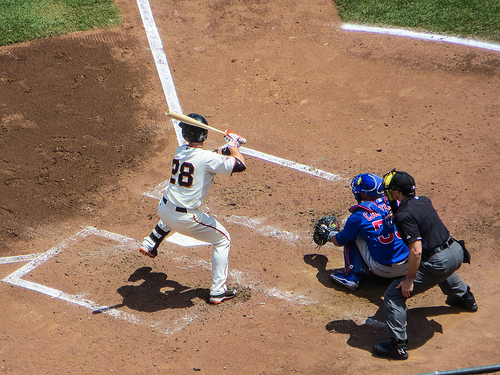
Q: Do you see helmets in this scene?
A: Yes, there is a helmet.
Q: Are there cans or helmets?
A: Yes, there is a helmet.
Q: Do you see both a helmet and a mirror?
A: No, there is a helmet but no mirrors.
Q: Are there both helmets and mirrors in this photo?
A: No, there is a helmet but no mirrors.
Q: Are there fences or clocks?
A: No, there are no fences or clocks.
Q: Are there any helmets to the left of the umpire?
A: Yes, there is a helmet to the left of the umpire.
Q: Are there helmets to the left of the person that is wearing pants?
A: Yes, there is a helmet to the left of the umpire.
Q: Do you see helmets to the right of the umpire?
A: No, the helmet is to the left of the umpire.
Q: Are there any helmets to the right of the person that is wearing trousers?
A: No, the helmet is to the left of the umpire.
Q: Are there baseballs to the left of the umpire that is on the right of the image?
A: No, there is a helmet to the left of the umpire.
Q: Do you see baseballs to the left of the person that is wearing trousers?
A: No, there is a helmet to the left of the umpire.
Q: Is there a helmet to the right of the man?
A: Yes, there is a helmet to the right of the man.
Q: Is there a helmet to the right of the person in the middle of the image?
A: Yes, there is a helmet to the right of the man.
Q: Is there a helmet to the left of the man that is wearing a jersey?
A: No, the helmet is to the right of the man.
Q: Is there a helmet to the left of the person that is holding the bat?
A: No, the helmet is to the right of the man.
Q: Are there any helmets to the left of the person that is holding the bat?
A: No, the helmet is to the right of the man.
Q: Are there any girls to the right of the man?
A: No, there is a helmet to the right of the man.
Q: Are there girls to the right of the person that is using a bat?
A: No, there is a helmet to the right of the man.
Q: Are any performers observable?
A: No, there are no performers.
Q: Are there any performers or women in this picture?
A: No, there are no performers or women.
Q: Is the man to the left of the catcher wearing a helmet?
A: Yes, the man is wearing a helmet.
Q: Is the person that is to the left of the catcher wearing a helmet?
A: Yes, the man is wearing a helmet.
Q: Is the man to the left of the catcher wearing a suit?
A: No, the man is wearing a helmet.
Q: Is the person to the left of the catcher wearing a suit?
A: No, the man is wearing a helmet.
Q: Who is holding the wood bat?
A: The man is holding the bat.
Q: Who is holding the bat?
A: The man is holding the bat.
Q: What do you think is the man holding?
A: The man is holding the bat.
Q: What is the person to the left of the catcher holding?
A: The man is holding the bat.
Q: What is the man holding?
A: The man is holding the bat.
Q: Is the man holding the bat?
A: Yes, the man is holding the bat.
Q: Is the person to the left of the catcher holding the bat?
A: Yes, the man is holding the bat.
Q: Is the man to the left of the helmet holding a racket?
A: No, the man is holding the bat.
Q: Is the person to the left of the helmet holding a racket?
A: No, the man is holding the bat.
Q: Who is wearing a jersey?
A: The man is wearing a jersey.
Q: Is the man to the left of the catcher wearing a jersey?
A: Yes, the man is wearing a jersey.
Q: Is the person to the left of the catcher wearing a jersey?
A: Yes, the man is wearing a jersey.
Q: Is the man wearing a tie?
A: No, the man is wearing a jersey.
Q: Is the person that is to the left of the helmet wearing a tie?
A: No, the man is wearing a jersey.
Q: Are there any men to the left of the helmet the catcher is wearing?
A: Yes, there is a man to the left of the helmet.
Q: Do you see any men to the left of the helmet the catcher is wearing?
A: Yes, there is a man to the left of the helmet.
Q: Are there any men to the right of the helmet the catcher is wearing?
A: No, the man is to the left of the helmet.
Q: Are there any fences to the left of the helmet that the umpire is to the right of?
A: No, there is a man to the left of the helmet.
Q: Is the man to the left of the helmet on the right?
A: Yes, the man is to the left of the helmet.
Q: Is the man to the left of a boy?
A: No, the man is to the left of the helmet.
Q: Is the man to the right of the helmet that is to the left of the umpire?
A: No, the man is to the left of the helmet.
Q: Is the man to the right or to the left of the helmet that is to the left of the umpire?
A: The man is to the left of the helmet.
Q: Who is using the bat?
A: The man is using the bat.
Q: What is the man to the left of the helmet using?
A: The man is using a bat.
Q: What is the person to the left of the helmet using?
A: The man is using a bat.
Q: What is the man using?
A: The man is using a bat.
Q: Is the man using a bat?
A: Yes, the man is using a bat.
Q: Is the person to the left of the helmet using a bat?
A: Yes, the man is using a bat.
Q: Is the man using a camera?
A: No, the man is using a bat.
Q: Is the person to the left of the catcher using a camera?
A: No, the man is using a bat.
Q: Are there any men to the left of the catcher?
A: Yes, there is a man to the left of the catcher.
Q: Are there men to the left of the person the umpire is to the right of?
A: Yes, there is a man to the left of the catcher.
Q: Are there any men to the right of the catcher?
A: No, the man is to the left of the catcher.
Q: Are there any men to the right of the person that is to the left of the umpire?
A: No, the man is to the left of the catcher.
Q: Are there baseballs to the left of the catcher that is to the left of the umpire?
A: No, there is a man to the left of the catcher.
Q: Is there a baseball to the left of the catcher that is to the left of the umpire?
A: No, there is a man to the left of the catcher.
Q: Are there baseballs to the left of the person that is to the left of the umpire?
A: No, there is a man to the left of the catcher.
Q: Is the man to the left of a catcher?
A: Yes, the man is to the left of a catcher.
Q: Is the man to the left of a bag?
A: No, the man is to the left of a catcher.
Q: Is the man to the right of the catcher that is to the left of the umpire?
A: No, the man is to the left of the catcher.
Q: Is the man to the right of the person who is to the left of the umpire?
A: No, the man is to the left of the catcher.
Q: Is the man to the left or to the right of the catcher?
A: The man is to the left of the catcher.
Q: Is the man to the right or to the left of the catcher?
A: The man is to the left of the catcher.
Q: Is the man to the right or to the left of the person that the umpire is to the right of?
A: The man is to the left of the catcher.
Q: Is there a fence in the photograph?
A: No, there are no fences.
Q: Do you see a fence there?
A: No, there are no fences.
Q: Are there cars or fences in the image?
A: No, there are no fences or cars.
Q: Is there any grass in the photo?
A: Yes, there is grass.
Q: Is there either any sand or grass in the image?
A: Yes, there is grass.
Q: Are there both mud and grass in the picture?
A: No, there is grass but no mud.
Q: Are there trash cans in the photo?
A: No, there are no trash cans.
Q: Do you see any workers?
A: No, there are no workers.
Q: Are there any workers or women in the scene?
A: No, there are no workers or women.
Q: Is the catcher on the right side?
A: Yes, the catcher is on the right of the image.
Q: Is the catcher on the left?
A: No, the catcher is on the right of the image.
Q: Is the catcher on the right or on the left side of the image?
A: The catcher is on the right of the image.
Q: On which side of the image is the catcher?
A: The catcher is on the right of the image.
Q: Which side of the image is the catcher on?
A: The catcher is on the right of the image.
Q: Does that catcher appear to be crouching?
A: Yes, the catcher is crouching.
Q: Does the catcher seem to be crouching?
A: Yes, the catcher is crouching.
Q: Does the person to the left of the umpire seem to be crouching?
A: Yes, the catcher is crouching.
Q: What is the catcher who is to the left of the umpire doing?
A: The catcher is crouching.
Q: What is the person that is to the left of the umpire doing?
A: The catcher is crouching.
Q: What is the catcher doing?
A: The catcher is crouching.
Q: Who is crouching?
A: The catcher is crouching.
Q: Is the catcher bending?
A: No, the catcher is crouching.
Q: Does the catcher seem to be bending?
A: No, the catcher is crouching.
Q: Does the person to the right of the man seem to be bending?
A: No, the catcher is crouching.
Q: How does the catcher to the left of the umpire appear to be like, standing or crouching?
A: The catcher is crouching.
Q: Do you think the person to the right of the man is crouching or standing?
A: The catcher is crouching.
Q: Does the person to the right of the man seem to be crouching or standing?
A: The catcher is crouching.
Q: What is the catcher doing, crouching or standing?
A: The catcher is crouching.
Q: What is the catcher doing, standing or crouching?
A: The catcher is crouching.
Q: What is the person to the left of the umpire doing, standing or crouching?
A: The catcher is crouching.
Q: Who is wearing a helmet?
A: The catcher is wearing a helmet.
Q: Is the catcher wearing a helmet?
A: Yes, the catcher is wearing a helmet.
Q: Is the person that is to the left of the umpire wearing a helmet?
A: Yes, the catcher is wearing a helmet.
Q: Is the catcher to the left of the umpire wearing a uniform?
A: No, the catcher is wearing a helmet.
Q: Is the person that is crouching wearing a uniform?
A: No, the catcher is wearing a helmet.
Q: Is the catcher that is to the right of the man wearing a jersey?
A: Yes, the catcher is wearing a jersey.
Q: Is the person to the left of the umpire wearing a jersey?
A: Yes, the catcher is wearing a jersey.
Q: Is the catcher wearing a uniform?
A: No, the catcher is wearing a jersey.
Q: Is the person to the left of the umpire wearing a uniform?
A: No, the catcher is wearing a jersey.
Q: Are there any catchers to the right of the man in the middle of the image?
A: Yes, there is a catcher to the right of the man.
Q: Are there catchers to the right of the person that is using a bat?
A: Yes, there is a catcher to the right of the man.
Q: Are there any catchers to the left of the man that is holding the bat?
A: No, the catcher is to the right of the man.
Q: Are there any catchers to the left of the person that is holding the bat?
A: No, the catcher is to the right of the man.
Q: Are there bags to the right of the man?
A: No, there is a catcher to the right of the man.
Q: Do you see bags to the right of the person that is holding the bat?
A: No, there is a catcher to the right of the man.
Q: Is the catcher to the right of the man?
A: Yes, the catcher is to the right of the man.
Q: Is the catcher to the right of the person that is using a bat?
A: Yes, the catcher is to the right of the man.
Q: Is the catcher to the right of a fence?
A: No, the catcher is to the right of the man.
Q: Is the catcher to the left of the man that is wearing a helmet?
A: No, the catcher is to the right of the man.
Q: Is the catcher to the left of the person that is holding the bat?
A: No, the catcher is to the right of the man.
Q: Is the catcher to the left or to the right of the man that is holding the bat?
A: The catcher is to the right of the man.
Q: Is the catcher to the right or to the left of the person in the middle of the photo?
A: The catcher is to the right of the man.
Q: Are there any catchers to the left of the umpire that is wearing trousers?
A: Yes, there is a catcher to the left of the umpire.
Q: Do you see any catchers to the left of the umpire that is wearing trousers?
A: Yes, there is a catcher to the left of the umpire.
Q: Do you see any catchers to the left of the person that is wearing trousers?
A: Yes, there is a catcher to the left of the umpire.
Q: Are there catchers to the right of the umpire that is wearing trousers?
A: No, the catcher is to the left of the umpire.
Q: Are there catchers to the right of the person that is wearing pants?
A: No, the catcher is to the left of the umpire.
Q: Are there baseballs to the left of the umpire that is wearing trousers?
A: No, there is a catcher to the left of the umpire.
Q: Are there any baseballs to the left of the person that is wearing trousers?
A: No, there is a catcher to the left of the umpire.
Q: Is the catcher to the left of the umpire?
A: Yes, the catcher is to the left of the umpire.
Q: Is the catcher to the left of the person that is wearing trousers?
A: Yes, the catcher is to the left of the umpire.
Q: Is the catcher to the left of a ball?
A: No, the catcher is to the left of the umpire.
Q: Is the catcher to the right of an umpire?
A: No, the catcher is to the left of an umpire.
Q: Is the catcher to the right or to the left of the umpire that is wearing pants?
A: The catcher is to the left of the umpire.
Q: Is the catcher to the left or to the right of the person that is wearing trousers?
A: The catcher is to the left of the umpire.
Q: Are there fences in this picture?
A: No, there are no fences.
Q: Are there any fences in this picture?
A: No, there are no fences.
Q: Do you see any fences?
A: No, there are no fences.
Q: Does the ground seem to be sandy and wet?
A: Yes, the ground is sandy and wet.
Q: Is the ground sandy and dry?
A: No, the ground is sandy but wet.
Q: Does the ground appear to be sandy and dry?
A: No, the ground is sandy but wet.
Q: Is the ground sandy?
A: Yes, the ground is sandy.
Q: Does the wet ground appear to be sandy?
A: Yes, the ground is sandy.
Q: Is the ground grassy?
A: No, the ground is sandy.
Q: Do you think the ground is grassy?
A: No, the ground is sandy.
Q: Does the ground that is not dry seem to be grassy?
A: No, the ground is sandy.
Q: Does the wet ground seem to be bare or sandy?
A: The ground is sandy.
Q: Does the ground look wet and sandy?
A: Yes, the ground is wet and sandy.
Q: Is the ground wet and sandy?
A: Yes, the ground is wet and sandy.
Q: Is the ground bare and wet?
A: No, the ground is wet but sandy.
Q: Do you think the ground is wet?
A: Yes, the ground is wet.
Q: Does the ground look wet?
A: Yes, the ground is wet.